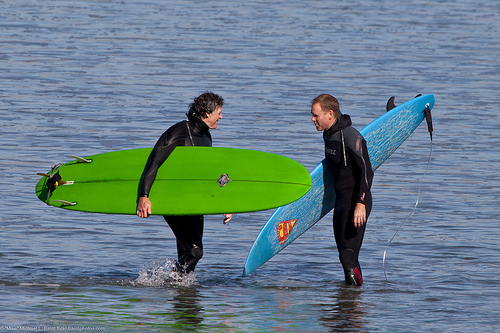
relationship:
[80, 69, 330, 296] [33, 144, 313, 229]
man holding surfboard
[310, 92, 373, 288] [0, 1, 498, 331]
man standing in water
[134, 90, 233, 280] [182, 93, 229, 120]
man with hair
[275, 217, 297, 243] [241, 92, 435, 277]
design on a surfboard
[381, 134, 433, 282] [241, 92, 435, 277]
line attached to a surfboard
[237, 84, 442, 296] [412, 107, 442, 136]
surfboard with fins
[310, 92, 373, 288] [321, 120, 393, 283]
man wearing a wetsuit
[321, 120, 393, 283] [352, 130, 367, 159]
wetsuit with markings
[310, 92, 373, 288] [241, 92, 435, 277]
man with surfboard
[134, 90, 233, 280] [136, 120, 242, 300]
man in wet suit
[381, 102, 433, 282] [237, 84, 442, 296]
line on surfboard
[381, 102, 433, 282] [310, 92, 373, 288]
line on man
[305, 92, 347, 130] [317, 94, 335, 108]
man with hair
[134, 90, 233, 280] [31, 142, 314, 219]
man carrying green board